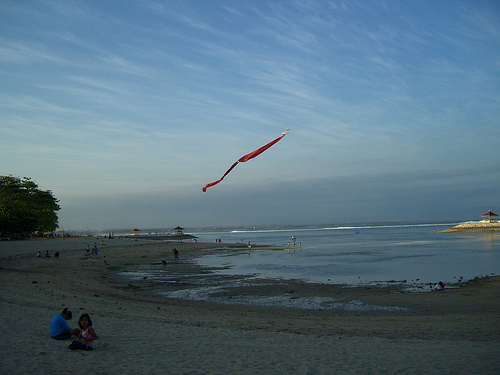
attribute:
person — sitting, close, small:
[43, 297, 79, 342]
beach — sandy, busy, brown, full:
[119, 233, 277, 356]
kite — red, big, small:
[212, 142, 266, 193]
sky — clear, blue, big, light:
[287, 51, 455, 191]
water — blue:
[310, 217, 406, 293]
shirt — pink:
[50, 311, 112, 341]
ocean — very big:
[232, 213, 394, 299]